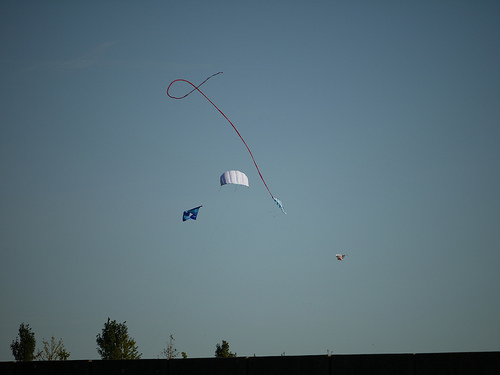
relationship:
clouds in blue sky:
[4, 3, 498, 365] [0, 0, 498, 358]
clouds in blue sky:
[4, 3, 498, 365] [335, 83, 463, 225]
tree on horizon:
[12, 322, 35, 362] [5, 349, 498, 364]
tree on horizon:
[37, 331, 67, 358] [5, 349, 498, 364]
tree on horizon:
[96, 314, 141, 359] [5, 349, 498, 364]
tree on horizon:
[212, 337, 236, 357] [5, 349, 498, 364]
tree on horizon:
[162, 330, 179, 359] [5, 349, 498, 364]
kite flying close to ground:
[203, 160, 244, 223] [2, 343, 492, 373]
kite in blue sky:
[218, 170, 251, 187] [0, 0, 498, 358]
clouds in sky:
[4, 3, 498, 365] [9, 11, 498, 277]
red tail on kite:
[165, 70, 274, 198] [271, 197, 286, 217]